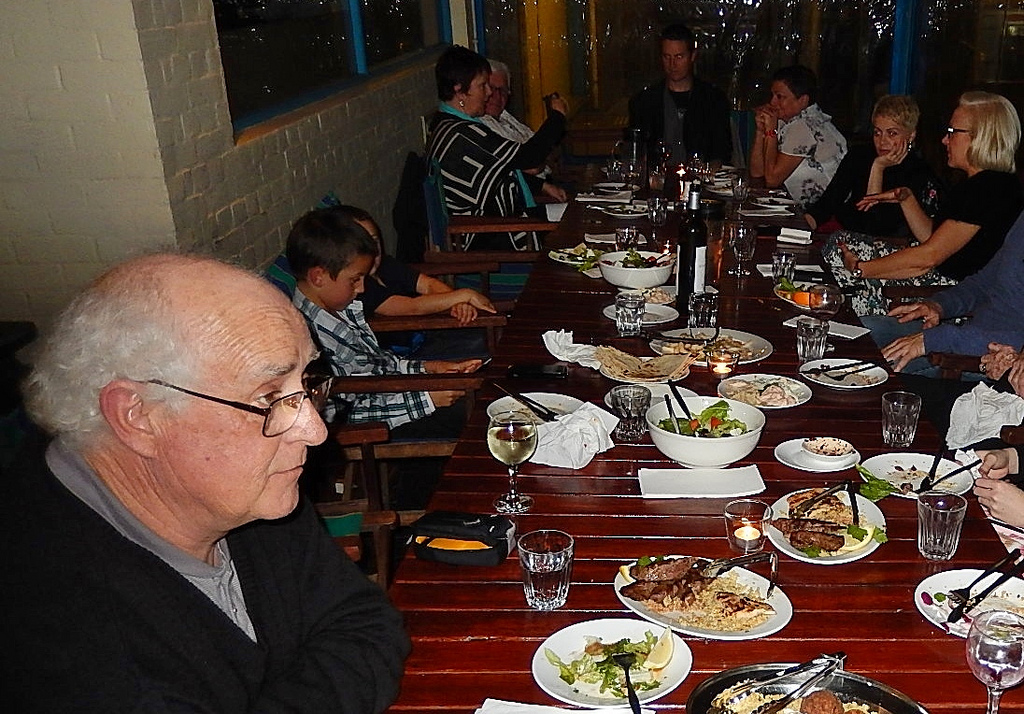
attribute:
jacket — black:
[0, 437, 418, 707]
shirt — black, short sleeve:
[933, 168, 1022, 289]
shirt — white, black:
[427, 105, 564, 248]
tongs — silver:
[700, 646, 838, 710]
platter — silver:
[673, 637, 926, 710]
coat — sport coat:
[625, 90, 753, 164]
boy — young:
[269, 224, 481, 434]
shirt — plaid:
[291, 305, 481, 435]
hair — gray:
[5, 246, 202, 433]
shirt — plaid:
[318, 303, 478, 427]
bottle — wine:
[672, 180, 721, 321]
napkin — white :
[641, 464, 765, 491]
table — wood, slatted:
[425, 177, 1023, 690]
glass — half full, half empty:
[523, 530, 585, 625]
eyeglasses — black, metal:
[176, 356, 348, 432]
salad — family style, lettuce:
[659, 404, 764, 447]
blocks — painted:
[28, 3, 216, 279]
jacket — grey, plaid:
[283, 290, 429, 426]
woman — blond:
[855, 104, 1021, 339]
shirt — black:
[935, 154, 1002, 273]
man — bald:
[0, 215, 427, 712]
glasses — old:
[109, 385, 341, 434]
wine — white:
[477, 417, 538, 463]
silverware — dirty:
[608, 645, 650, 712]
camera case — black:
[399, 512, 513, 571]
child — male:
[275, 209, 482, 447]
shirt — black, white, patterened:
[427, 105, 548, 260]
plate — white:
[530, 615, 695, 709]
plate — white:
[617, 550, 795, 650]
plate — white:
[908, 571, 1023, 643]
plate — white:
[761, 483, 891, 566]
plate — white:
[857, 450, 976, 505]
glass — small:
[509, 524, 579, 615]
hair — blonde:
[952, 87, 1022, 176]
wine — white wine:
[485, 422, 535, 466]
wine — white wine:
[487, 427, 535, 467]